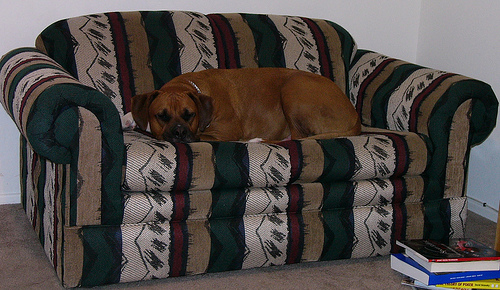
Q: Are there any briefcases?
A: No, there are no briefcases.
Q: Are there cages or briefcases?
A: No, there are no briefcases or cages.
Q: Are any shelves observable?
A: No, there are no shelves.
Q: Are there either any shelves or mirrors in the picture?
A: No, there are no shelves or mirrors.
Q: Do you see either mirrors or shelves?
A: No, there are no shelves or mirrors.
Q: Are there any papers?
A: No, there are no papers.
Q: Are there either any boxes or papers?
A: No, there are no papers or boxes.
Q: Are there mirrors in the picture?
A: No, there are no mirrors.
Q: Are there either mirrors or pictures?
A: No, there are no mirrors or pictures.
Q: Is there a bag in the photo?
A: No, there are no bags.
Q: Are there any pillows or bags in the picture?
A: No, there are no bags or pillows.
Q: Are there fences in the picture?
A: No, there are no fences.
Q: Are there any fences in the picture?
A: No, there are no fences.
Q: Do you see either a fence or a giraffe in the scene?
A: No, there are no fences or giraffes.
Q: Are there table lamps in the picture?
A: No, there are no table lamps.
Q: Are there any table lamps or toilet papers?
A: No, there are no table lamps or toilet papers.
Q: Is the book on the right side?
A: Yes, the book is on the right of the image.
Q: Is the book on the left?
A: No, the book is on the right of the image.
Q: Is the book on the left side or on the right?
A: The book is on the right of the image.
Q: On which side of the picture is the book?
A: The book is on the right of the image.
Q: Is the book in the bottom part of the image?
A: Yes, the book is in the bottom of the image.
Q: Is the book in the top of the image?
A: No, the book is in the bottom of the image.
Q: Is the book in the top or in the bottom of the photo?
A: The book is in the bottom of the image.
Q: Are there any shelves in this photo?
A: No, there are no shelves.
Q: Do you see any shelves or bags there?
A: No, there are no shelves or bags.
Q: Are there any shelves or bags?
A: No, there are no shelves or bags.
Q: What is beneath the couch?
A: The carpet is beneath the couch.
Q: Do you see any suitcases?
A: No, there are no suitcases.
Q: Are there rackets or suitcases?
A: No, there are no suitcases or rackets.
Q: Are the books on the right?
A: Yes, the books are on the right of the image.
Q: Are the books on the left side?
A: No, the books are on the right of the image.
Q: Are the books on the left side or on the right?
A: The books are on the right of the image.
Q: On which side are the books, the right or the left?
A: The books are on the right of the image.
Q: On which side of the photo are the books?
A: The books are on the right of the image.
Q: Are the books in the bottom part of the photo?
A: Yes, the books are in the bottom of the image.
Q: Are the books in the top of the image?
A: No, the books are in the bottom of the image.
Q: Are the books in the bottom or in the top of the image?
A: The books are in the bottom of the image.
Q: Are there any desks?
A: No, there are no desks.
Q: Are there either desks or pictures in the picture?
A: No, there are no desks or pictures.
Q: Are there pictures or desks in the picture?
A: No, there are no desks or pictures.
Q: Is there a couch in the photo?
A: Yes, there is a couch.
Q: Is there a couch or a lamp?
A: Yes, there is a couch.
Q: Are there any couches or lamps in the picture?
A: Yes, there is a couch.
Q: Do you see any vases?
A: No, there are no vases.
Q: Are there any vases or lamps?
A: No, there are no vases or lamps.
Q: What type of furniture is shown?
A: The furniture is a couch.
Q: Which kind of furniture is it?
A: The piece of furniture is a couch.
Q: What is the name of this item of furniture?
A: This is a couch.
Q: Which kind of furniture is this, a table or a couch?
A: This is a couch.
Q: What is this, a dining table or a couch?
A: This is a couch.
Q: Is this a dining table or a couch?
A: This is a couch.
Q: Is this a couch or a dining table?
A: This is a couch.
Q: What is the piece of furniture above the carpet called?
A: The piece of furniture is a couch.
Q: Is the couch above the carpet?
A: Yes, the couch is above the carpet.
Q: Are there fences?
A: No, there are no fences.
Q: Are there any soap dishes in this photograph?
A: No, there are no soap dishes.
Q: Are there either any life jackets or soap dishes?
A: No, there are no soap dishes or life jackets.